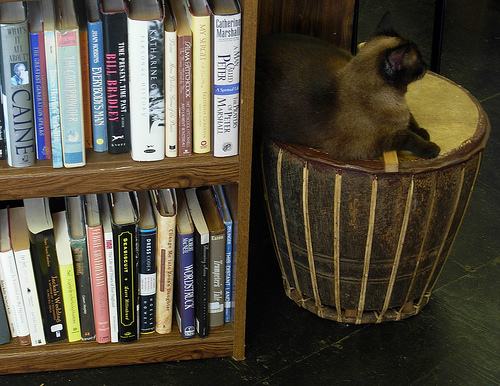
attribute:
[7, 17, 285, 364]
bookcase — wooden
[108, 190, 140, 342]
book — black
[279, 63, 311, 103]
fur — dark gray